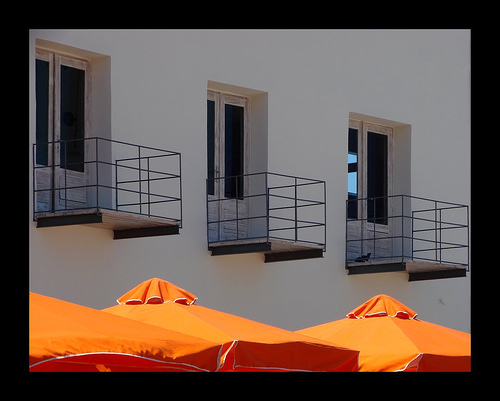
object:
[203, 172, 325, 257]
balcony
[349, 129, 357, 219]
window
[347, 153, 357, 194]
light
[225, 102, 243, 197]
window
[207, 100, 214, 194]
window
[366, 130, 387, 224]
window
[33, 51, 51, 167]
window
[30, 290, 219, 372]
tent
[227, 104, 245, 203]
window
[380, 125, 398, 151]
ground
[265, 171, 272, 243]
pole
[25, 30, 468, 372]
house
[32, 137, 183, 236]
balconies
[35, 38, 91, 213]
doors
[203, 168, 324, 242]
balcony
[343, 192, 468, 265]
balcony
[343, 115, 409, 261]
rooms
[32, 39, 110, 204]
rooms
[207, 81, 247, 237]
room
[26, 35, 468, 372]
outdoor area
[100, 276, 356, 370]
orange tent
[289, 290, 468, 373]
orange tent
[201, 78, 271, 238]
apartment doors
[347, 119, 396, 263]
doors